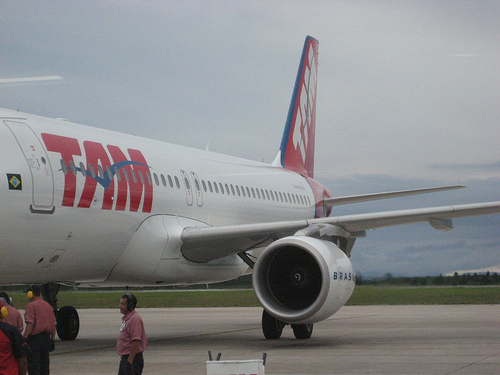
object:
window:
[58, 145, 81, 176]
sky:
[1, 2, 112, 78]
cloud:
[418, 76, 458, 120]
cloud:
[334, 12, 383, 82]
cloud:
[198, 34, 241, 96]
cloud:
[9, 50, 64, 107]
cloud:
[123, 32, 158, 74]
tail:
[272, 35, 319, 174]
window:
[95, 162, 108, 181]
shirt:
[113, 312, 149, 357]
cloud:
[435, 161, 498, 178]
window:
[292, 192, 303, 206]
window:
[57, 159, 72, 177]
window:
[104, 158, 114, 188]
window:
[251, 185, 260, 202]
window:
[165, 170, 174, 190]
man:
[16, 281, 59, 372]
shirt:
[18, 295, 59, 341]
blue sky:
[312, 176, 498, 279]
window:
[170, 172, 182, 190]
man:
[115, 288, 147, 375]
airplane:
[0, 34, 498, 339]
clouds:
[321, 35, 488, 165]